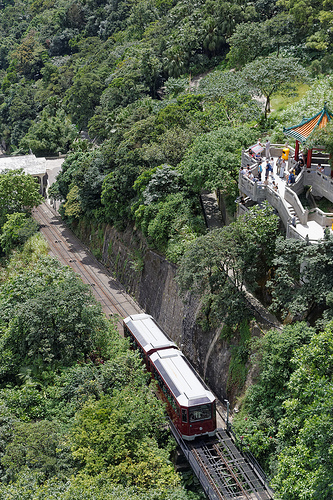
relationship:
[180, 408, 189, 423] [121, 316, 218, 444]
window on train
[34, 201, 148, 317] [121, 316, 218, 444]
track for train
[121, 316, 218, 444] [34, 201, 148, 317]
train on track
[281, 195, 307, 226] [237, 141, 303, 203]
steps go up to platform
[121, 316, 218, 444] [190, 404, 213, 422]
train has a windshield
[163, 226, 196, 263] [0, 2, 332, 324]
bush on hillside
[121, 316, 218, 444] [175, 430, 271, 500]
train on a bridge